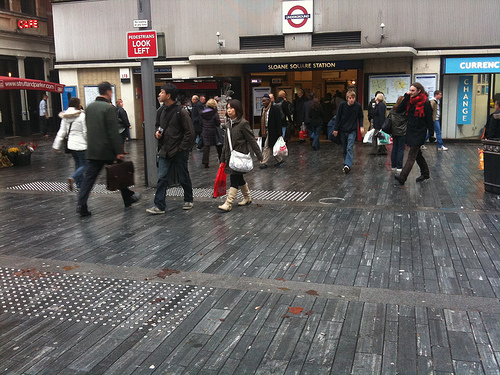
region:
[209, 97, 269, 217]
woman walking on walkway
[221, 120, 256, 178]
woman wearing white handbag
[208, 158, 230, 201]
woman holding red shopping bag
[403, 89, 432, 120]
man wearing red scarf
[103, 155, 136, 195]
man holding black briefcase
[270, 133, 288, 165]
man holding shopping bags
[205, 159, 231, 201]
red plastic bag in hand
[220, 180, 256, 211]
woman wearing white boots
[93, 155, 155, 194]
man holding brown brief case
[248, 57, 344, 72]
name of train station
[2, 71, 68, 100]
red cover on front of building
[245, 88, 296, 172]
man walking with white bags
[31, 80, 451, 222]
people walking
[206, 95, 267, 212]
a woman carrying a red plastic bag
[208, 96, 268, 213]
a person wearing boots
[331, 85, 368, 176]
a person wearing blue jeans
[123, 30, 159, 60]
a warning sign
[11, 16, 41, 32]
a word cafe on wall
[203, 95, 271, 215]
woman carrying white shoulder bag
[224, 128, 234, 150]
white strap of shoulder bag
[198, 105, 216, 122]
a hood of the coat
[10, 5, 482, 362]
people walking on plaza at train entrance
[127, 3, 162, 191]
gray pole with red and white sign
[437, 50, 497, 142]
open entry to business handling money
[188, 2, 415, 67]
subway logo over extended roof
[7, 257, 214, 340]
rows of gray dots on ground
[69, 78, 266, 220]
people walking around a pole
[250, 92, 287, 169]
man in dark jacket carrying bundles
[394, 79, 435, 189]
man in red scarf talking on phone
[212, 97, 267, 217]
woman with white shoulder bag carrying red bag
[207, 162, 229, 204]
A red bag in a woman's hand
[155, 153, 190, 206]
Black pants on a man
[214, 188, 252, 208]
White boots on a woman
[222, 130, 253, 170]
A white pocketbook on a woman's shoulder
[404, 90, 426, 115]
A red scarf around a person's neck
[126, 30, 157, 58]
A red sign on a post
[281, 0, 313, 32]
A white sign with a red circle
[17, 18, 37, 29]
A red cafe sign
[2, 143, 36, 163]
A pot with flowers in it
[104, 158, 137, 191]
A briefcase in a man's hand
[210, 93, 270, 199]
Woman carrying a red bag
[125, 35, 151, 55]
"LOOK LEFT" written on a sign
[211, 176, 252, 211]
A pair of white boots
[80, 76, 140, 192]
Man carrying a briefcase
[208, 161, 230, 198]
A red shopping bag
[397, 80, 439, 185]
A man with a red scarf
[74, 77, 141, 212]
A man carrying a briefcase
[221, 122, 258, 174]
A white purse worn by a woman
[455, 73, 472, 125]
A blue sign that reads change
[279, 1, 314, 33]
A white sign with a red circle on it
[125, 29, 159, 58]
A red sign with the words look left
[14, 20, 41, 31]
A red sign that reads cafe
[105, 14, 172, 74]
RED AND WHITE SIGN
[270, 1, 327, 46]
WHITE AND RED SIGN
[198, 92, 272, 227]
LADY WALKING HOLDING RED BAG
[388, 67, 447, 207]
MAN WALKING ON SIDE WALK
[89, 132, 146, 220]
MAN CARRYING BRIEF CASE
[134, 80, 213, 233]
MAN WALKING ALONG STREET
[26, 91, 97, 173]
LADY WEARING WHITE JACKET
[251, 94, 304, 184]
MAN HOLDING BAGS